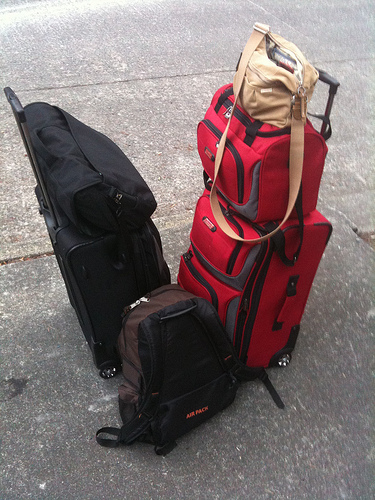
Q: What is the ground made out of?
A: Concrete.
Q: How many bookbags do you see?
A: One.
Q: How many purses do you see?
A: 1.